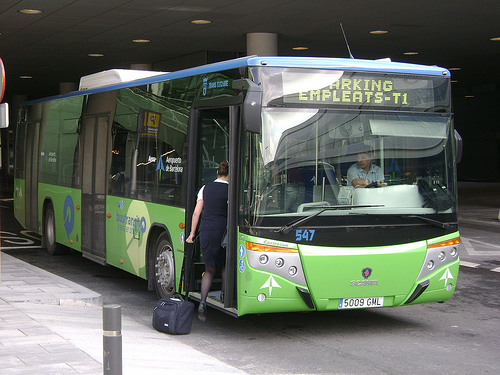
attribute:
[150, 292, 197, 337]
bag — black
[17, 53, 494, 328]
bus — large, green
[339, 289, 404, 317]
plate — black, white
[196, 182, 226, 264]
dress — blue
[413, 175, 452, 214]
backpack — black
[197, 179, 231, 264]
dress — blue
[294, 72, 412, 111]
lcd screen — green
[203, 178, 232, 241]
vest — blue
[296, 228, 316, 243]
number — blue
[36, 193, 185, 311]
wheels — black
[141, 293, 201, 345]
bag — blue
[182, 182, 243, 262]
dress — blue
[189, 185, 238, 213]
shirt — white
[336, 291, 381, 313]
license plate — black, white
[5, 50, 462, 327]
bus — black, green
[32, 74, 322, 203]
bus — green